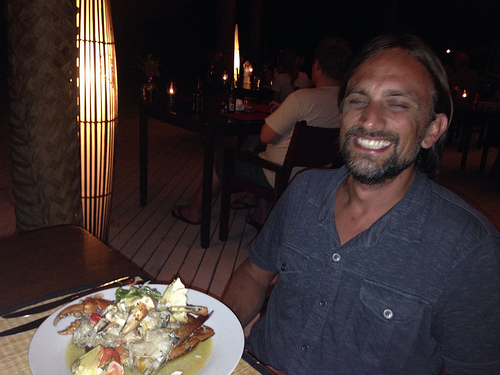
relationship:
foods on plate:
[58, 269, 208, 372] [26, 273, 246, 373]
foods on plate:
[52, 275, 216, 373] [26, 273, 246, 373]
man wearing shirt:
[215, 36, 498, 374] [241, 163, 499, 372]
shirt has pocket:
[241, 163, 499, 372] [345, 276, 429, 374]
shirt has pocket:
[241, 163, 499, 372] [266, 249, 307, 330]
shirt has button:
[241, 163, 499, 372] [331, 248, 341, 266]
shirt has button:
[241, 163, 499, 372] [381, 303, 392, 320]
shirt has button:
[241, 163, 499, 372] [318, 298, 329, 308]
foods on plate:
[52, 275, 216, 373] [31, 284, 247, 374]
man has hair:
[215, 36, 498, 374] [329, 31, 453, 171]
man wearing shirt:
[172, 35, 352, 231] [257, 79, 342, 188]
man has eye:
[215, 36, 498, 374] [347, 97, 367, 107]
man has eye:
[215, 36, 498, 374] [388, 95, 408, 113]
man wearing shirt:
[167, 35, 358, 220] [258, 86, 341, 188]